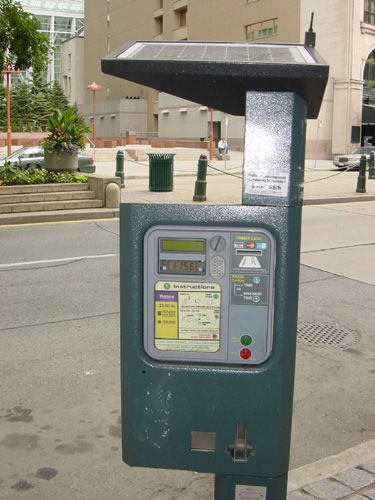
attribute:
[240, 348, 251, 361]
button — red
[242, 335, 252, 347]
button — green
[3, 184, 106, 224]
stairs — in back, stone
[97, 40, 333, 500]
meter — electric, solar powered, green, old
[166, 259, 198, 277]
clock — digital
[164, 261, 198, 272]
time — current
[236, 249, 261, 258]
card slot — horizontal, metal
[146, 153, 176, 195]
trash can — green, between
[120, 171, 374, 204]
sidewalk — stone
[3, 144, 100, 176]
car — green, parked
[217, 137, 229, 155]
person — sitting, seated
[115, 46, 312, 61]
solar panel — hanging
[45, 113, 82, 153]
plants — potted, green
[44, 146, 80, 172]
planter — cement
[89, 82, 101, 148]
street light — outdoors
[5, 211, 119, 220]
curb — stone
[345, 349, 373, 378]
stains — oily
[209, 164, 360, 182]
chain — curved